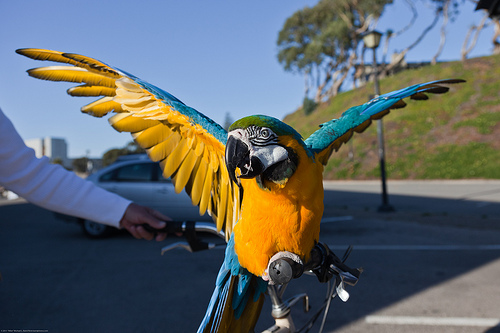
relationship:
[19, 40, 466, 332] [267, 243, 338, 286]
parrot on top of handle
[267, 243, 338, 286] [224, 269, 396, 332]
handle attached to bicycle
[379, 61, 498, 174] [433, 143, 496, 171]
hill covered in grass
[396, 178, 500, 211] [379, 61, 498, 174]
sidewalk below hill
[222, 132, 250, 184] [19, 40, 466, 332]
beak attached to parrot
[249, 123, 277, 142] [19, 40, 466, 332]
eye attached to parrot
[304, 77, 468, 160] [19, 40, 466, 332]
wing attached to parrot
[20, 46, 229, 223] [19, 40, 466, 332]
wing attached to parrot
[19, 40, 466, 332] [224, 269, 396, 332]
parrot sitting on top of bicycle